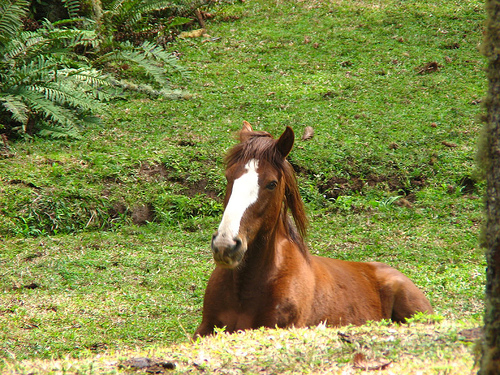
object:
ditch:
[85, 283, 187, 366]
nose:
[209, 235, 242, 255]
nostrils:
[233, 238, 240, 249]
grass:
[367, 87, 489, 137]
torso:
[288, 226, 387, 328]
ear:
[273, 126, 295, 161]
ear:
[239, 119, 260, 141]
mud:
[67, 195, 154, 236]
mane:
[238, 130, 309, 238]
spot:
[210, 154, 259, 257]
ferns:
[0, 0, 188, 141]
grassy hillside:
[0, 2, 500, 185]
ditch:
[1, 146, 484, 240]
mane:
[223, 140, 246, 176]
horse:
[191, 117, 433, 339]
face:
[211, 157, 286, 270]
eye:
[265, 181, 277, 191]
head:
[210, 125, 295, 270]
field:
[0, 0, 497, 373]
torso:
[202, 247, 317, 330]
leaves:
[34, 77, 95, 104]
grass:
[195, 329, 286, 365]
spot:
[348, 108, 439, 206]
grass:
[2, 244, 178, 372]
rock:
[117, 353, 179, 371]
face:
[213, 156, 280, 267]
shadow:
[192, 316, 492, 374]